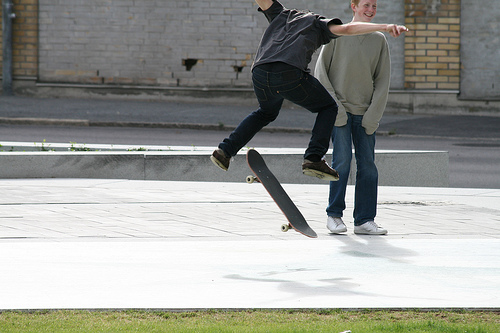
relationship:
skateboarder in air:
[212, 2, 409, 194] [222, 186, 266, 232]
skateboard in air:
[239, 146, 320, 252] [222, 186, 266, 232]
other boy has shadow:
[354, 0, 405, 97] [338, 236, 420, 278]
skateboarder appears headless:
[221, 2, 345, 193] [298, 0, 324, 18]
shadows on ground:
[256, 228, 414, 304] [65, 183, 138, 281]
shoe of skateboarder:
[212, 145, 234, 174] [212, 2, 409, 194]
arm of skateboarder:
[334, 22, 418, 45] [212, 2, 409, 194]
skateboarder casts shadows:
[212, 2, 409, 194] [256, 228, 414, 304]